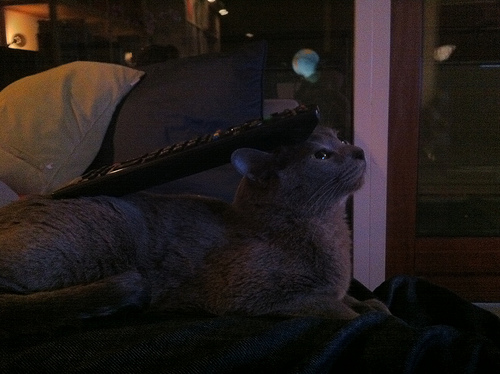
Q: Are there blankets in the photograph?
A: Yes, there is a blanket.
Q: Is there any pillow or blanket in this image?
A: Yes, there is a blanket.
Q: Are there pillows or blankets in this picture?
A: Yes, there is a blanket.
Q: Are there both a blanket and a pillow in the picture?
A: Yes, there are both a blanket and a pillow.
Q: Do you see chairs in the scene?
A: No, there are no chairs.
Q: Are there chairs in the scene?
A: No, there are no chairs.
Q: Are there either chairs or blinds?
A: No, there are no chairs or blinds.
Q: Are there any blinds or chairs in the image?
A: No, there are no chairs or blinds.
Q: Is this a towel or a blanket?
A: This is a blanket.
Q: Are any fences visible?
A: No, there are no fences.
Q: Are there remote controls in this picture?
A: Yes, there is a remote control.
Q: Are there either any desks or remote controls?
A: Yes, there is a remote control.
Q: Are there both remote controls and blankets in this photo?
A: Yes, there are both a remote control and a blanket.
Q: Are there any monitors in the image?
A: No, there are no monitors.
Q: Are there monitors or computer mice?
A: No, there are no monitors or computer mice.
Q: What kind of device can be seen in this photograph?
A: The device is a remote control.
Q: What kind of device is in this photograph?
A: The device is a remote control.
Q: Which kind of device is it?
A: The device is a remote control.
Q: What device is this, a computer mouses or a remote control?
A: That is a remote control.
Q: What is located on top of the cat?
A: The remote control is on top of the cat.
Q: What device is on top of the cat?
A: The device is a remote control.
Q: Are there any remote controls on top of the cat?
A: Yes, there is a remote control on top of the cat.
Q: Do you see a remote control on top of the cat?
A: Yes, there is a remote control on top of the cat.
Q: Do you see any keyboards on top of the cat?
A: No, there is a remote control on top of the cat.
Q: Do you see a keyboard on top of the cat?
A: No, there is a remote control on top of the cat.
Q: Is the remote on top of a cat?
A: Yes, the remote is on top of a cat.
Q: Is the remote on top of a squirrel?
A: No, the remote is on top of a cat.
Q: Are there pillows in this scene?
A: Yes, there is a pillow.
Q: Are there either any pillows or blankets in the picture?
A: Yes, there is a pillow.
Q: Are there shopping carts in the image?
A: No, there are no shopping carts.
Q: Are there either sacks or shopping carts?
A: No, there are no shopping carts or sacks.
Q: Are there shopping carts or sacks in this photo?
A: No, there are no shopping carts or sacks.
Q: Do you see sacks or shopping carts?
A: No, there are no shopping carts or sacks.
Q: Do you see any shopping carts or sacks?
A: No, there are no shopping carts or sacks.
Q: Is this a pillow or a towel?
A: This is a pillow.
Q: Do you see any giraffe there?
A: No, there are no giraffes.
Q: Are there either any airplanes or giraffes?
A: No, there are no giraffes or airplanes.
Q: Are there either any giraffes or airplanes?
A: No, there are no giraffes or airplanes.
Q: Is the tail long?
A: Yes, the tail is long.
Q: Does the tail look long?
A: Yes, the tail is long.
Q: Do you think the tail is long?
A: Yes, the tail is long.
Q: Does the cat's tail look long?
A: Yes, the tail is long.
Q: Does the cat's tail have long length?
A: Yes, the tail is long.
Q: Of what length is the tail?
A: The tail is long.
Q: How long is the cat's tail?
A: The tail is long.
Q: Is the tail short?
A: No, the tail is long.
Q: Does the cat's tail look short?
A: No, the tail is long.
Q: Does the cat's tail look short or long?
A: The tail is long.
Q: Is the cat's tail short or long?
A: The tail is long.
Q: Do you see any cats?
A: Yes, there is a cat.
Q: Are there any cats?
A: Yes, there is a cat.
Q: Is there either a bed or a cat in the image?
A: Yes, there is a cat.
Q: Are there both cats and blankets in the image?
A: Yes, there are both a cat and a blanket.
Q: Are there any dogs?
A: No, there are no dogs.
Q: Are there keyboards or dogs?
A: No, there are no dogs or keyboards.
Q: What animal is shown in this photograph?
A: The animal is a cat.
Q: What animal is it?
A: The animal is a cat.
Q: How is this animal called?
A: That is a cat.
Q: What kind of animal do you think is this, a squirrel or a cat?
A: That is a cat.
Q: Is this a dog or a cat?
A: This is a cat.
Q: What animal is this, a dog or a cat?
A: This is a cat.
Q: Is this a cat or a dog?
A: This is a cat.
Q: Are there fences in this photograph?
A: No, there are no fences.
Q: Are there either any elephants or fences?
A: No, there are no fences or elephants.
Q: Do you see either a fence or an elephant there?
A: No, there are no fences or elephants.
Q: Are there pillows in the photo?
A: Yes, there is a pillow.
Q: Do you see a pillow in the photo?
A: Yes, there is a pillow.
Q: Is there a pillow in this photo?
A: Yes, there is a pillow.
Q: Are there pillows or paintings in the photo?
A: Yes, there is a pillow.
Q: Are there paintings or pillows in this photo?
A: Yes, there is a pillow.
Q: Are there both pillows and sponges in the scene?
A: No, there is a pillow but no sponges.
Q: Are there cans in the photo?
A: No, there are no cans.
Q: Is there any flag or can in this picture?
A: No, there are no cans or flags.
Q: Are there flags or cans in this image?
A: No, there are no cans or flags.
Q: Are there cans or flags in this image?
A: No, there are no cans or flags.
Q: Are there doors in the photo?
A: Yes, there is a door.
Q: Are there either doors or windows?
A: Yes, there is a door.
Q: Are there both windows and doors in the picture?
A: Yes, there are both a door and windows.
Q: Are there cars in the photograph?
A: No, there are no cars.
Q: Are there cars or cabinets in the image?
A: No, there are no cars or cabinets.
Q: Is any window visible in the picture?
A: Yes, there is a window.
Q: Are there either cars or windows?
A: Yes, there is a window.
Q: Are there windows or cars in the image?
A: Yes, there is a window.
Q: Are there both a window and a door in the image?
A: Yes, there are both a window and a door.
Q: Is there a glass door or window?
A: Yes, there is a glass window.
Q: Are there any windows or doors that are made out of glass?
A: Yes, the window is made of glass.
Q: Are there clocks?
A: No, there are no clocks.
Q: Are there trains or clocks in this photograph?
A: No, there are no clocks or trains.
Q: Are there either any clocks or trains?
A: No, there are no clocks or trains.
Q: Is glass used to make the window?
A: Yes, the window is made of glass.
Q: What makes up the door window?
A: The window is made of glass.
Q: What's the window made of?
A: The window is made of glass.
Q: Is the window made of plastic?
A: No, the window is made of glass.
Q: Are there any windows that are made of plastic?
A: No, there is a window but it is made of glass.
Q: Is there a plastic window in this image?
A: No, there is a window but it is made of glass.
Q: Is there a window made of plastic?
A: No, there is a window but it is made of glass.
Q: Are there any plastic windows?
A: No, there is a window but it is made of glass.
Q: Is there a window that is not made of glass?
A: No, there is a window but it is made of glass.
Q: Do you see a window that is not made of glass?
A: No, there is a window but it is made of glass.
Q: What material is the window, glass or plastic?
A: The window is made of glass.